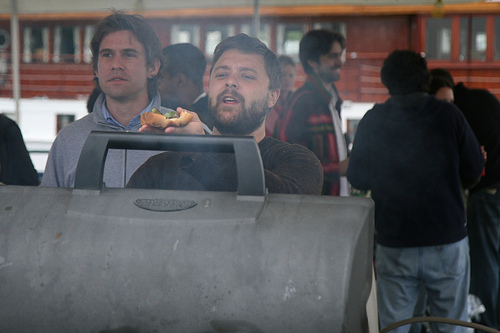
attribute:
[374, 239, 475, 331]
jeans — blue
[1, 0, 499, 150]
building — red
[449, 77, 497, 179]
shirt — black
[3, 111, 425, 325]
grill — metal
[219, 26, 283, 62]
hair — brown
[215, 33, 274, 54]
hair — short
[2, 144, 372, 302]
grill — dark gray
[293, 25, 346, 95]
beard — dark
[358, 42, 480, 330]
man — smiling